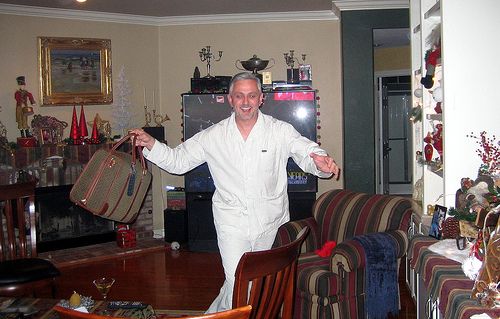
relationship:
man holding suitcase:
[211, 62, 309, 258] [75, 142, 159, 236]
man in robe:
[211, 62, 309, 258] [206, 132, 293, 219]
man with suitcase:
[211, 62, 309, 258] [75, 142, 159, 236]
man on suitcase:
[211, 62, 309, 258] [75, 142, 159, 236]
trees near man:
[63, 106, 108, 146] [211, 62, 309, 258]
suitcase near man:
[75, 142, 159, 236] [211, 62, 309, 258]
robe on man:
[206, 132, 293, 219] [211, 62, 309, 258]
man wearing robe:
[211, 62, 309, 258] [206, 132, 293, 219]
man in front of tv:
[211, 62, 309, 258] [283, 90, 326, 141]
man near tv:
[211, 62, 309, 258] [283, 90, 326, 141]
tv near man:
[283, 90, 326, 141] [211, 62, 309, 258]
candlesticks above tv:
[188, 37, 309, 93] [177, 89, 331, 257]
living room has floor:
[2, 5, 436, 314] [57, 256, 209, 297]